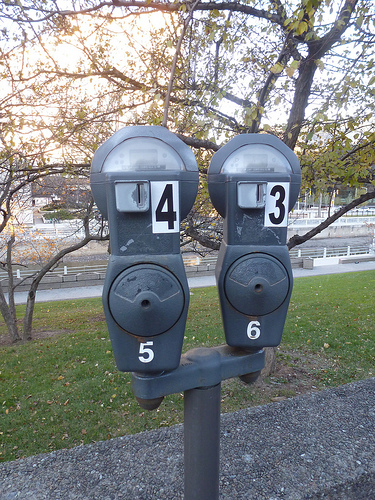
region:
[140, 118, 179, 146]
edge of a post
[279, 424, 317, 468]
part of a floor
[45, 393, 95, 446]
part of a ground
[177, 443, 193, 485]
edge of a post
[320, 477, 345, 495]
edge of a road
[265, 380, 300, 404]
edge of a path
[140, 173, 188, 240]
Number 4 on the meter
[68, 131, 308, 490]
The meters are black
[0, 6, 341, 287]
Trees behind the meters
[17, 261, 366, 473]
Brown leaves on the grass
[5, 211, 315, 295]
Water behind the fence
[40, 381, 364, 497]
Black asphalt path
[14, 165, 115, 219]
Building with a black roof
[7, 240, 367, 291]
Long white fence with rails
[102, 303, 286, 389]
Numbers in white on meter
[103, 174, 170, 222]
The coin slot is grey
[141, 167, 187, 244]
The number four on the meter.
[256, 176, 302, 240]
The number three on a parking meter.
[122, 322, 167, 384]
The number five on a parking meter.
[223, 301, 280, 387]
The number six on a parking meter.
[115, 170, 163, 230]
A coin slot on a parking meter next tot he number four.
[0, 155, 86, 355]
A tree that branches three ways at the ground.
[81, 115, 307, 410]
Two parking meters.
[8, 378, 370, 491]
A solid surface, that may be a wall and may be in contact with the parking meter pole.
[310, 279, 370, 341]
An area of green grass.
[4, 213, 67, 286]
Yellow leaves on a tree to the left of the parking meter.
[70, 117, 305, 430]
TWO PARKING METERS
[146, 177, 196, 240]
THE NUMBER FOUR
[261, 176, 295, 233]
THE NUMBER THREE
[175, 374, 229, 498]
THE METAL POLE OF A PARKING METER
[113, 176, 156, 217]
A COIN SLOT ON A PARKING METER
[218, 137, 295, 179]
THE DIGITAL DISPLAY OF A PARKING METER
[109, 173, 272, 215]
TWO PARKING METER COIN SLOTS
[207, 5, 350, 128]
THE BRANCHES OF A TREE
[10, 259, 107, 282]
A WHITE FENCE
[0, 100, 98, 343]
A PICTURE OF A TREE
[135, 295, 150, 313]
a hole in the parking mater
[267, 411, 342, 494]
gravel in the sidewalk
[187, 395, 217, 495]
a sturdy gray pole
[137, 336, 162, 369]
a white number on the meter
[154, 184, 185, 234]
a black number on a white sticker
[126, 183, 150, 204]
the coin slot of the machine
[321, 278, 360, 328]
green grass on the ground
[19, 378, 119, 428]
brown leaves scattered on the grass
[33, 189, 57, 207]
a white house with a black roof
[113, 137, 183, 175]
the domed display window on the meter